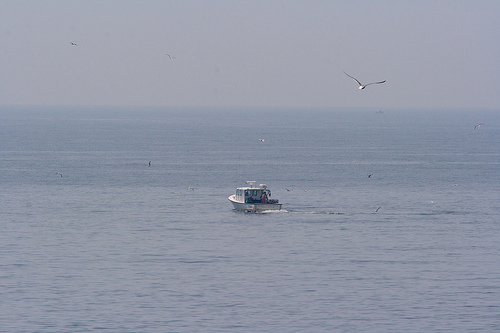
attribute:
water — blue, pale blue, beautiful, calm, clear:
[1, 105, 500, 332]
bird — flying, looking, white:
[339, 71, 386, 92]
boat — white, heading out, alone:
[226, 179, 282, 215]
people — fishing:
[260, 192, 268, 203]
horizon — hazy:
[2, 80, 498, 122]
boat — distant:
[257, 135, 266, 143]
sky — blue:
[1, 0, 500, 112]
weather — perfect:
[2, 2, 500, 329]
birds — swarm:
[67, 38, 387, 94]